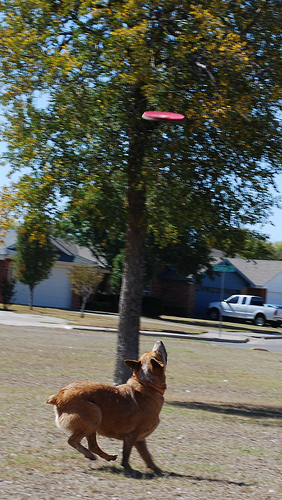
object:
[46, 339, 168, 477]
dog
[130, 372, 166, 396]
collar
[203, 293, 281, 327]
truck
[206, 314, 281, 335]
driveway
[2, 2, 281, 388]
tree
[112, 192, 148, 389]
trunk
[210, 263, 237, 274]
street sign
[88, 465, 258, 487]
shadow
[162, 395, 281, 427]
shadow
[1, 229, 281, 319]
houses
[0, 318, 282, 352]
street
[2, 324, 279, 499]
field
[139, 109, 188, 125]
frisbee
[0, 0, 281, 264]
leaves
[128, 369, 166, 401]
neck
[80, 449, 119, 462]
back feet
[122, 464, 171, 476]
front feet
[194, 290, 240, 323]
door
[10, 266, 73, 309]
door